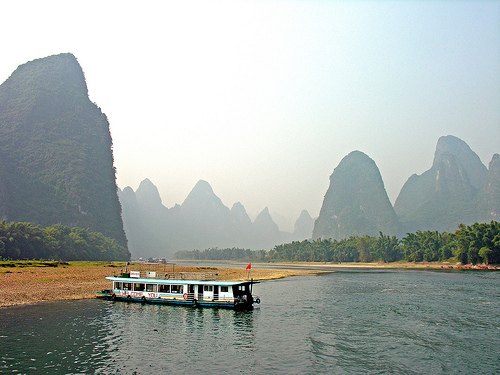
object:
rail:
[181, 290, 200, 308]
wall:
[408, 173, 441, 208]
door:
[197, 284, 219, 298]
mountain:
[253, 203, 278, 240]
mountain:
[229, 199, 253, 241]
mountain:
[184, 175, 229, 242]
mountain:
[131, 175, 179, 232]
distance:
[129, 14, 485, 253]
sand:
[1, 263, 151, 310]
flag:
[243, 262, 253, 276]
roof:
[105, 279, 256, 286]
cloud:
[0, 1, 497, 261]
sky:
[0, 0, 498, 231]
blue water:
[3, 261, 493, 370]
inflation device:
[162, 273, 172, 280]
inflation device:
[181, 290, 188, 301]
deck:
[103, 273, 255, 288]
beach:
[0, 258, 335, 307]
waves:
[277, 299, 486, 368]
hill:
[4, 52, 133, 261]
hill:
[116, 173, 157, 260]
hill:
[306, 147, 405, 247]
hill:
[389, 132, 489, 225]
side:
[222, 247, 493, 271]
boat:
[97, 260, 258, 316]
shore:
[1, 255, 498, 305]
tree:
[10, 217, 59, 262]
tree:
[359, 221, 413, 263]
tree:
[439, 226, 485, 270]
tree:
[299, 235, 326, 263]